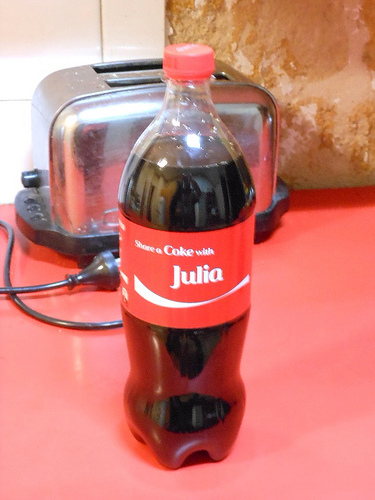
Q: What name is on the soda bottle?
A: Julia.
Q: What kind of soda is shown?
A: Coke.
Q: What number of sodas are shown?
A: 1.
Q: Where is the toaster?
A: Behind the soda.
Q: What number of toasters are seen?
A: 1.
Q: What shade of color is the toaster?
A: Silver.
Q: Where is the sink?
A: Not in the photo.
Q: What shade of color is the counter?
A: Red.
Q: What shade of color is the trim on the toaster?
A: Black.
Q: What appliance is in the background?
A: A toaster.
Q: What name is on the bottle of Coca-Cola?
A: Julia.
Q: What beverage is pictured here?
A: Coca-Cola.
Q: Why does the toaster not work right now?
A: Not plugged in.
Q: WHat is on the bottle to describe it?
A: A red label.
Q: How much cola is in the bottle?
A: It is full.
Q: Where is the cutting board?
A: Behind the toaster.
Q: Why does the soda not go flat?
A: Because the cap is on.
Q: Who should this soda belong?
A: Julia.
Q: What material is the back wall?
A: White tile with grey grout.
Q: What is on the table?
A: A bottle of coke.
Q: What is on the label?
A: White writing.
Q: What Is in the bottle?
A: Dark liquid.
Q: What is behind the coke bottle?
A: A toaster.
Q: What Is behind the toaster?
A: A wall.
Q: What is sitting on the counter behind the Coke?
A: Toaster.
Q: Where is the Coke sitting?
A: Counter.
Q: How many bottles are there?
A: One.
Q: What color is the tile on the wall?
A: White.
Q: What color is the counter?
A: Red.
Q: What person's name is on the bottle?
A: Julia.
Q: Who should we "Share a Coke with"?
A: Julia.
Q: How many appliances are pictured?
A: One.